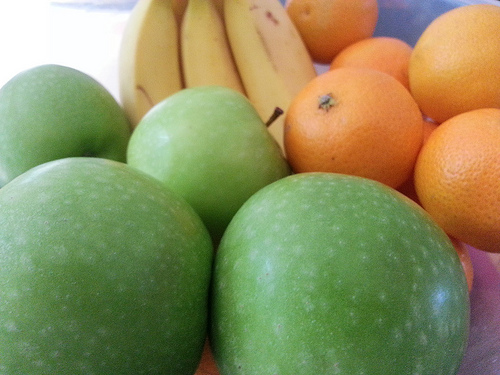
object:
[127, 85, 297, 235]
apple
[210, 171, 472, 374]
apple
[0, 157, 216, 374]
apple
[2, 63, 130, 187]
apple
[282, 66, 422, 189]
orange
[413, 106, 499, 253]
orange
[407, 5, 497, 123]
orange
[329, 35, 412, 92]
orange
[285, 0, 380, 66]
orange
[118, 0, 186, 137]
bananas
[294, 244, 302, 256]
spot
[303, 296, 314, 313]
spot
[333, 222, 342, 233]
spot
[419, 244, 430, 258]
spot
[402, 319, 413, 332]
spot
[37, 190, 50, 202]
spot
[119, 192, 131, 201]
spot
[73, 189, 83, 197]
spot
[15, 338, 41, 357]
spot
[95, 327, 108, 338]
spot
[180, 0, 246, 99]
banana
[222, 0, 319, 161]
banana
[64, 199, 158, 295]
surface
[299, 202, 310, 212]
spot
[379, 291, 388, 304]
spot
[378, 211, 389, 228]
spot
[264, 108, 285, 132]
stem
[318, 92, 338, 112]
stem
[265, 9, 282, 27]
bruise